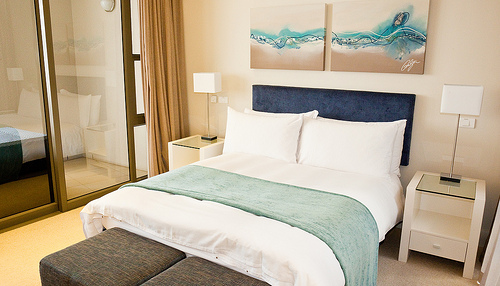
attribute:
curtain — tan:
[140, 0, 187, 175]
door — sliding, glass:
[2, 2, 174, 222]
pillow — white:
[226, 106, 316, 168]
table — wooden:
[396, 177, 498, 248]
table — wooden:
[394, 165, 488, 278]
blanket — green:
[124, 157, 389, 267]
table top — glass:
[413, 170, 488, 203]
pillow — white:
[303, 116, 407, 175]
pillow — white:
[298, 115, 398, 175]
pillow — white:
[223, 109, 300, 163]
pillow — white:
[243, 108, 315, 163]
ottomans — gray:
[36, 222, 259, 284]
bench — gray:
[21, 212, 271, 282]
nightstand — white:
[165, 131, 224, 172]